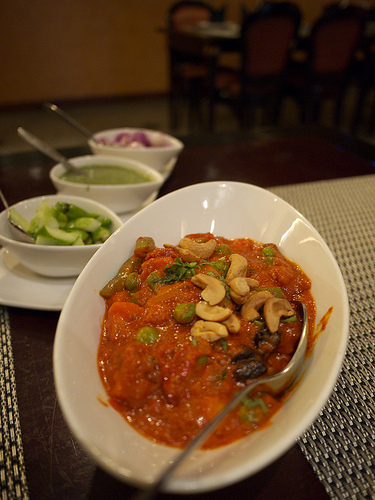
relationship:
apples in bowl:
[21, 197, 92, 245] [18, 247, 64, 285]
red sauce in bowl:
[112, 360, 143, 404] [36, 163, 355, 499]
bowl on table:
[48, 177, 351, 495] [0, 175, 373, 486]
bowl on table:
[0, 194, 125, 275] [0, 175, 373, 486]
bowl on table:
[49, 154, 165, 214] [0, 175, 373, 486]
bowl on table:
[87, 127, 183, 173] [0, 175, 373, 486]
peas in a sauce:
[123, 273, 158, 291] [95, 232, 315, 450]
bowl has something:
[48, 177, 351, 495] [91, 128, 170, 147]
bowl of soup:
[48, 177, 351, 495] [98, 232, 315, 451]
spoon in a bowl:
[136, 297, 317, 490] [36, 163, 355, 499]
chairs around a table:
[209, 11, 364, 102] [175, 19, 294, 71]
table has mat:
[312, 167, 374, 342] [327, 174, 364, 216]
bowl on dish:
[0, 194, 125, 275] [0, 246, 80, 311]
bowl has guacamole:
[37, 142, 184, 215] [55, 150, 158, 192]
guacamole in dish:
[59, 163, 156, 184] [87, 121, 186, 174]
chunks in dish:
[16, 206, 111, 240] [1, 194, 123, 315]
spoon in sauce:
[10, 120, 95, 186] [52, 154, 159, 195]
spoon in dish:
[123, 289, 317, 498] [41, 175, 326, 470]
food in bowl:
[82, 207, 314, 437] [16, 154, 370, 478]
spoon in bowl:
[130, 300, 313, 498] [54, 158, 337, 493]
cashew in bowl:
[189, 272, 225, 307] [36, 163, 355, 499]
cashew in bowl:
[262, 294, 295, 331] [0, 194, 125, 275]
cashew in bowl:
[177, 235, 217, 260] [49, 154, 165, 214]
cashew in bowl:
[188, 320, 228, 343] [87, 127, 183, 173]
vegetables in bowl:
[104, 235, 162, 298] [36, 163, 355, 499]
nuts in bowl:
[164, 231, 297, 344] [36, 163, 355, 499]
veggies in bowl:
[8, 202, 111, 244] [0, 194, 125, 275]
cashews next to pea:
[194, 275, 262, 332] [147, 298, 192, 339]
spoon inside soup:
[130, 300, 313, 498] [98, 234, 314, 451]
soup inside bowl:
[98, 234, 314, 451] [48, 178, 343, 466]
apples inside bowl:
[6, 196, 113, 245] [0, 194, 125, 275]